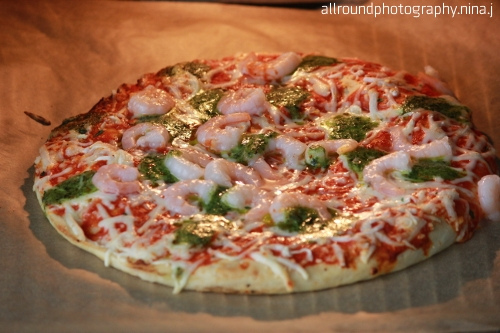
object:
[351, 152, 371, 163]
green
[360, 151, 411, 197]
basil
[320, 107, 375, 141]
broccoli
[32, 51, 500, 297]
pizza